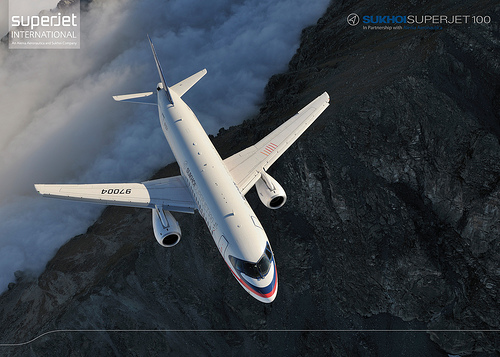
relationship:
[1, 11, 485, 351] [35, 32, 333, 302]
terrain under a airplane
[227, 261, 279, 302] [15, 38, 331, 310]
front on a plane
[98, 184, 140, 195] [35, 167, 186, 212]
numbers on a wing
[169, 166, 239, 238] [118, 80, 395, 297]
shadow on a plane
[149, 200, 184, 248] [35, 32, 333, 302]
engine on a airplane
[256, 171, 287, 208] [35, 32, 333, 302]
jet's engine on a airplane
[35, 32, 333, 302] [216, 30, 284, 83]
airplane above clouds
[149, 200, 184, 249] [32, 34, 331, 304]
engine on an airplane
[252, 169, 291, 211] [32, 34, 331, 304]
engine on an airplane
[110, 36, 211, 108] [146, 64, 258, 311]
tail on an airplane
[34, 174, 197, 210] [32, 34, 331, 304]
wing on a airplane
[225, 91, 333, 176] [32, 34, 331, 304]
wing on a airplane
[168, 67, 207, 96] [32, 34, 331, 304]
wing on a airplane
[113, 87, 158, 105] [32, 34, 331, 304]
wing on a airplane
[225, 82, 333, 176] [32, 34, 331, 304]
wing on an airplane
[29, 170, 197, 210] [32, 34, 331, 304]
wing on an airplane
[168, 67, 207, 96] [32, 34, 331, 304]
wing on an airplane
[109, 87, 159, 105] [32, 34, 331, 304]
wing on an airplane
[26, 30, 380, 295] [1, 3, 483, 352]
airplane over a mountains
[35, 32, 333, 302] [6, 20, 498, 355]
airplane in sky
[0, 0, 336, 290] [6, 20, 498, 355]
cloud in sky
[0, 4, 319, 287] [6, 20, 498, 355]
clouds in sky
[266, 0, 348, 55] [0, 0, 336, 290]
sky in cloud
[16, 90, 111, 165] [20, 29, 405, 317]
clouds in sky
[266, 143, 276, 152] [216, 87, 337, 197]
stripe on a wing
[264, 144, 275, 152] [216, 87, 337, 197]
stripe on a wing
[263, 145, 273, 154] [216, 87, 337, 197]
stripe on a wing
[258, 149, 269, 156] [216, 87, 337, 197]
stripe on a wing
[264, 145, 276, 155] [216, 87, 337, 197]
stripe on a wing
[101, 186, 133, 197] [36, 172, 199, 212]
number on a wing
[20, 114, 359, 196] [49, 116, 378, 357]
top view of plane in flight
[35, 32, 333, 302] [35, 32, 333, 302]
airplane a passenger airplane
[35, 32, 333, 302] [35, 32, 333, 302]
airplane in airplane